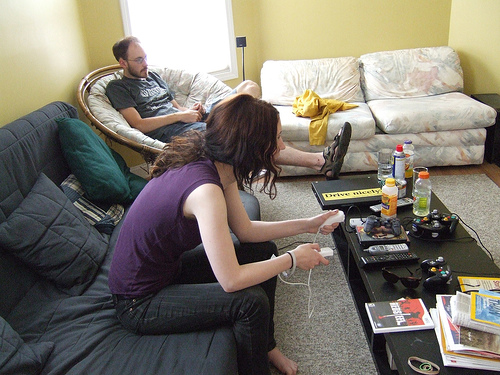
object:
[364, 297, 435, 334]
game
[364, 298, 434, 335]
box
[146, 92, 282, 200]
hair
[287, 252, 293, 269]
black band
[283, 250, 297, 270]
wrist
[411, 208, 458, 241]
game controllers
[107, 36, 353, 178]
man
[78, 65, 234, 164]
chair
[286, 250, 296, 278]
bracelet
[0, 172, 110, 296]
throw pillow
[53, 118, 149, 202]
throw pillow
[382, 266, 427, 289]
sun glasses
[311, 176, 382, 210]
case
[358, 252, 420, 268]
remote control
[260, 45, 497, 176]
sofa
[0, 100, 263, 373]
couch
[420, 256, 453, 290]
controller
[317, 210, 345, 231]
controller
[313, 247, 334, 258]
controller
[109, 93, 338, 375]
girl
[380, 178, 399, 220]
bottle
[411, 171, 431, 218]
bottle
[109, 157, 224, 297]
purple shirt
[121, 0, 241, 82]
window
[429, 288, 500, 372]
magazine stack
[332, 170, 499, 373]
coffee table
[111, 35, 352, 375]
couple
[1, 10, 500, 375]
living room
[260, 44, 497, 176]
love seat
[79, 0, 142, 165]
wall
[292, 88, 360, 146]
clothing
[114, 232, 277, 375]
jeans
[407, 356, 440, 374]
bands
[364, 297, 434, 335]
wii game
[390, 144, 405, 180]
wd-40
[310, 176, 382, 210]
laptop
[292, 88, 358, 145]
blanket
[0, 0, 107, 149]
wall